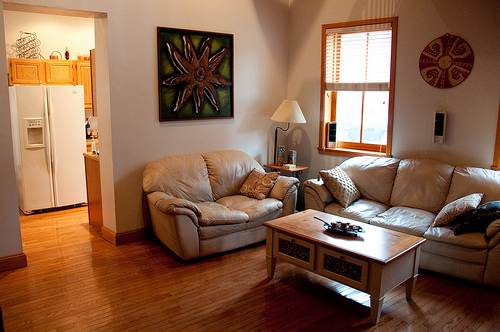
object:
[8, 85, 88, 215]
refrigerator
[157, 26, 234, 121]
painting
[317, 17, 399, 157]
window frame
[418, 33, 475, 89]
decoration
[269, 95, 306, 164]
lamp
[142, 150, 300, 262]
couch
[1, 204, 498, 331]
floor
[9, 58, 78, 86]
storage space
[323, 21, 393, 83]
mini blinds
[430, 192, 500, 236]
two pillows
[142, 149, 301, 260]
love seat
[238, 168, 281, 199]
one pillow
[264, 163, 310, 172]
end table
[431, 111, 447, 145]
speaker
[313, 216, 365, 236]
tray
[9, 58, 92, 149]
cabinets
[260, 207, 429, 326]
center table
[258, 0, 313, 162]
corner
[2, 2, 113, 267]
background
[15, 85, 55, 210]
door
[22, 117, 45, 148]
water dispenser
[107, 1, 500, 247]
wall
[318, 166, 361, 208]
pillows